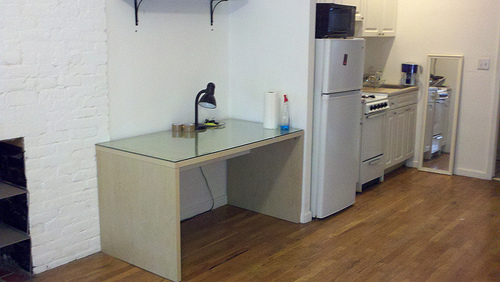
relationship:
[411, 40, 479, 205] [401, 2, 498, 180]
mirror against wall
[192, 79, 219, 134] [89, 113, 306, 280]
lamp on a desk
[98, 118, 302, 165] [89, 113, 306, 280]
top for desk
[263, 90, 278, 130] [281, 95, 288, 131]
paper towel and bottle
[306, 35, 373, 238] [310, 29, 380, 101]
refrigerator with top freezer door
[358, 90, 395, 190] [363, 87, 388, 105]
oven and range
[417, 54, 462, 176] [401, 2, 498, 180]
mirror leaning against wall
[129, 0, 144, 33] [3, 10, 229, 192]
shelf bracket attached to wall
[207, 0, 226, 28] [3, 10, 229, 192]
shelf bracket attached to wall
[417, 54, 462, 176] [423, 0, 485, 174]
mirror standing against wall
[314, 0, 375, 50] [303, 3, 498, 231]
microwave in kitchen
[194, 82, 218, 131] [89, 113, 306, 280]
lamp on desk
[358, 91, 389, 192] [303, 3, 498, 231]
gas stove in kitchen